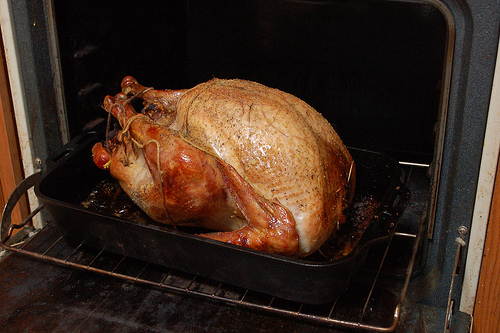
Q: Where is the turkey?
A: In the oven.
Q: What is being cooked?
A: The turkey.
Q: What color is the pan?
A: Black.